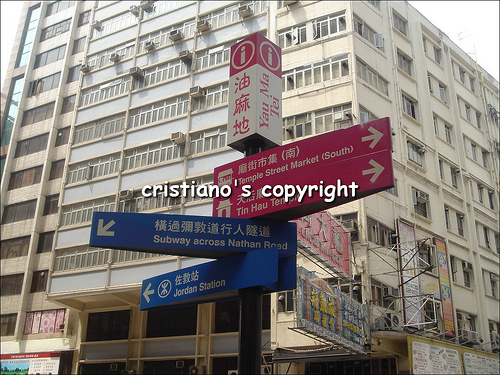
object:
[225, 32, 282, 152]
sign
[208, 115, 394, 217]
sign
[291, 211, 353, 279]
sign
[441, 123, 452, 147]
window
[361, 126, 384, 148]
arrow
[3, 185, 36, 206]
concrete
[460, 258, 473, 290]
windows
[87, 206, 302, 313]
signs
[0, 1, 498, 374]
building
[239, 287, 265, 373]
pole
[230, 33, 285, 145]
sign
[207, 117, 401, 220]
signs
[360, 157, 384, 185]
arrow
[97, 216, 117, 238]
arrow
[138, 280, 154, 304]
arrow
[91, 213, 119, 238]
down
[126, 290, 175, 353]
right